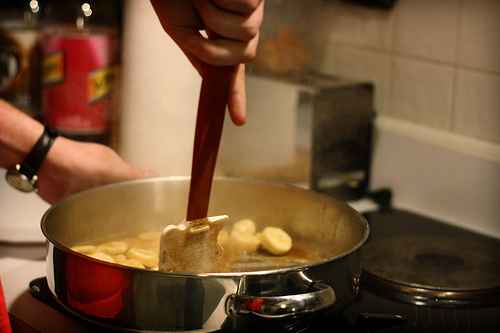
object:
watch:
[6, 125, 58, 194]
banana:
[67, 219, 291, 272]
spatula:
[159, 64, 234, 274]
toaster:
[213, 69, 378, 201]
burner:
[364, 233, 497, 309]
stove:
[28, 209, 499, 332]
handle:
[226, 280, 337, 320]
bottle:
[42, 0, 124, 147]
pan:
[41, 174, 370, 331]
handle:
[186, 66, 236, 221]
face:
[6, 168, 45, 194]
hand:
[5, 124, 160, 205]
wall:
[246, 5, 498, 241]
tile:
[245, 0, 498, 147]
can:
[40, 28, 120, 138]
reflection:
[54, 247, 128, 321]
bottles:
[2, 0, 123, 147]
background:
[0, 0, 498, 208]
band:
[20, 123, 59, 178]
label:
[40, 25, 122, 136]